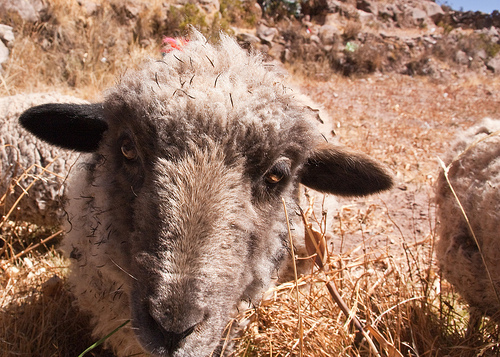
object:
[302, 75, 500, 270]
ground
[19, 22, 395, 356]
sheep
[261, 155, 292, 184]
eye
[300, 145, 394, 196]
ear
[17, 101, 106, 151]
ear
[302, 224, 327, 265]
leaf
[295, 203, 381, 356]
branch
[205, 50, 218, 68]
strand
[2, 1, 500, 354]
field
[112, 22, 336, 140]
fur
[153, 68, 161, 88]
debris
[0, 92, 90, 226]
sheep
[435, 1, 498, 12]
sky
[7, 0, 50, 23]
rock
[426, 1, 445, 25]
rock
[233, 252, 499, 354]
grass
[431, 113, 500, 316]
sheep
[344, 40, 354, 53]
foliage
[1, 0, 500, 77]
hillside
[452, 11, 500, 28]
trees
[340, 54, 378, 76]
shrub